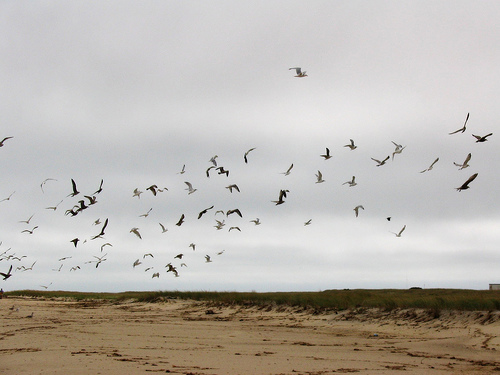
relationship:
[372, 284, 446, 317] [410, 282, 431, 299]
grass has something on it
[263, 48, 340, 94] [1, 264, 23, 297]
bird has 2 lifted wings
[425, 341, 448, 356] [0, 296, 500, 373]
part of sand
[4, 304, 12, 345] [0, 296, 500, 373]
edge of sand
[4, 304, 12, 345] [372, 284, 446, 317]
edge of grass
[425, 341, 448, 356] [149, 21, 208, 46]
part of sky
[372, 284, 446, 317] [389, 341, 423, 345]
grass behind sand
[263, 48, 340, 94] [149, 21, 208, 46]
bird against sky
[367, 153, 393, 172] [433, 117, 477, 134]
bird with outstretched wings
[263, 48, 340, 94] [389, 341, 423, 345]
bird over sand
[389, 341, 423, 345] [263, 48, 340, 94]
sand under bird